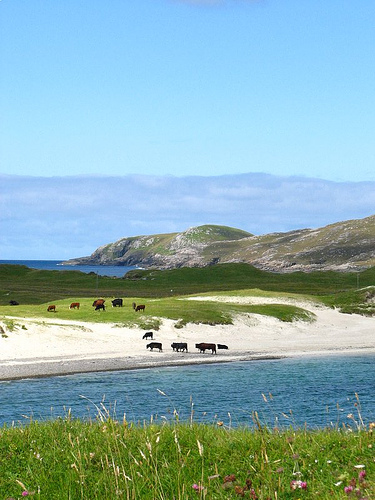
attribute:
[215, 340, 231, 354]
cow — black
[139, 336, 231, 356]
cows — black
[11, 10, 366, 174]
sky — blue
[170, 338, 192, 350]
animal — large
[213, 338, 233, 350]
animal — large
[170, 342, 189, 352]
animal — large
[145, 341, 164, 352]
animal — large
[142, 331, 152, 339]
animal — large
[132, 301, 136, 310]
animal — large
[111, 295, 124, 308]
animal — large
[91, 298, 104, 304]
animal — large, brown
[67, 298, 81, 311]
animal — brown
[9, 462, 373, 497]
flowers — pink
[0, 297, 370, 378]
beaches — white, sandy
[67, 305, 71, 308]
head — white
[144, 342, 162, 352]
cow — black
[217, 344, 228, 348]
cow — black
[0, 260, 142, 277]
waters — blue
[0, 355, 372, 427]
water — rippling, blue, gentle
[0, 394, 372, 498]
grass — green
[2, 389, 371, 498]
plants — pink, flowering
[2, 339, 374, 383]
shoreline — long, straight, gentle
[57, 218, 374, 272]
hill — rocky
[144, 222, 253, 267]
hill — grassy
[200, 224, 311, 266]
hill — grassy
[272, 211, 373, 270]
hill — grassy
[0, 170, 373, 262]
cloud — low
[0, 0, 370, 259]
sky — clear, blue, cloudy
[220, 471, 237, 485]
flower — small, purple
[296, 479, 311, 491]
flower — small, purple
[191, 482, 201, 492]
flower — small, purple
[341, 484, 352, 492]
flower — small, purple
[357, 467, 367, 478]
flower — small, purple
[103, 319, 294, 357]
shore — white sandy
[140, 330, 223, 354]
cow —  large black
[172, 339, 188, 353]
cow —  large black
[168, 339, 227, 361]
cow —  large black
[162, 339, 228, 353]
cow — grazing, Two brown 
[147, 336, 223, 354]
cow — large brown 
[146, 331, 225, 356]
cow — large brown 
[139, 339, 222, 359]
cow — large brown 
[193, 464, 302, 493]
thistle —  small purple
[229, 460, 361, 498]
flowers — pink , bunch 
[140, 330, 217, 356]
cow — distance, black 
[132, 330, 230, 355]
cow — black , distance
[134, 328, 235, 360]
cow — distance, black 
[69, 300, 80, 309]
cow — distant, brown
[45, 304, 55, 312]
cow — brown, distant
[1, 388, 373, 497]
hillside — green, grassy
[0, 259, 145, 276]
water — blue, distant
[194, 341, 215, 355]
cow — brown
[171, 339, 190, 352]
cow — brown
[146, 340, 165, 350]
cow — brown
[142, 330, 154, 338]
cow — brown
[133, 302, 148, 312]
cow — brown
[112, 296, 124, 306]
cow — black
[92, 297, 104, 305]
cow — brown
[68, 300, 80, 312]
cow — brown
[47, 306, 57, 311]
cow — brown